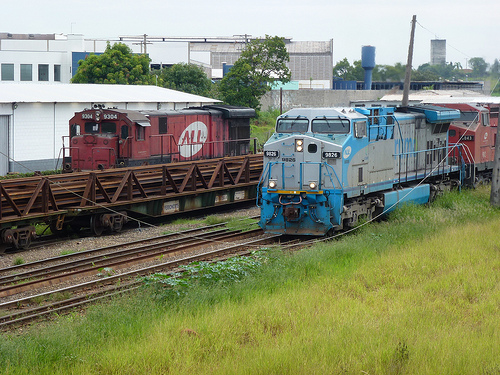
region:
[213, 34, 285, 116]
a tree in a distance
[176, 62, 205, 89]
a tree in a distance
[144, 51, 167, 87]
a tree in a distance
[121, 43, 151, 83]
a tree in a distance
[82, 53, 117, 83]
a tree in a distance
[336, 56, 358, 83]
a tree in a distance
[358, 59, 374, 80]
a tree in a distance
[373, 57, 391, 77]
a tree in a distance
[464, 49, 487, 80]
a tree in a distance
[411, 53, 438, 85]
a tree in a distance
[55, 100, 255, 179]
The red engine by itself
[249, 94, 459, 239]
The blue engine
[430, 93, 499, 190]
The car behind the blue engine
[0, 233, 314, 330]
The tracks in front of the blue engine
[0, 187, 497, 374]
The grass field next to the blue train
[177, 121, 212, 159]
The white circle on the red engine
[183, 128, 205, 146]
The red writing in the white circle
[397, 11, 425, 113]
The wood telephone pole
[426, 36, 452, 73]
The silo in the background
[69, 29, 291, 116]
The trees behind the building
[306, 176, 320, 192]
the head light of a train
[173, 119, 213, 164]
a white label on the train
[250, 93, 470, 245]
a blue and gray train engine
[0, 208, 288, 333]
two sets of train tracks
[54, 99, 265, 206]
a red and black train engine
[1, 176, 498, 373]
a green patch of grass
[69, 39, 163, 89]
a green tree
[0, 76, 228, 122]
a white roof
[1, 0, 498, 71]
a cloudy gray sky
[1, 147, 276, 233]
a train load of wood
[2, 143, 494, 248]
Utility wire sagging down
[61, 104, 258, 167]
Red and black train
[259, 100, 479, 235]
Gray and blue train without any cars attached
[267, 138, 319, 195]
Lights are on on front of train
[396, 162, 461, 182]
Walking platform on side of blue train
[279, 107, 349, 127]
Four windshield wipers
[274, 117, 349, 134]
Train engineer's windows to see through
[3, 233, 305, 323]
Sections of two sets of train tracks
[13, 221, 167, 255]
Gravel on the ground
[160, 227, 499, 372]
Little hill of grass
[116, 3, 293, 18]
white clouds in the sky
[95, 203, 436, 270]
long rope over train track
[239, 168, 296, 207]
white lights on train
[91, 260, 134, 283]
green bush growing on track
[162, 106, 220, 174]
large white logo on red train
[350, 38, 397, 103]
large blue water tower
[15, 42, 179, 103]
white roof on building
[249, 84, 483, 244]
blue and gray train on track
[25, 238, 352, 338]
large train track on the ground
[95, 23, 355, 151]
large cluster of green trees